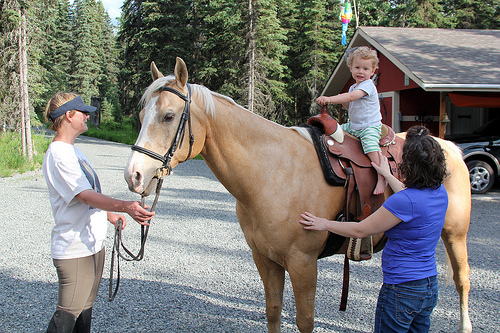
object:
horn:
[322, 96, 330, 111]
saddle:
[310, 101, 411, 218]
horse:
[125, 56, 473, 332]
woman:
[44, 91, 156, 333]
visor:
[48, 94, 97, 120]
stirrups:
[346, 234, 376, 261]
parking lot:
[0, 154, 499, 331]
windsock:
[337, 1, 354, 46]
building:
[316, 26, 500, 147]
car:
[454, 140, 500, 194]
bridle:
[131, 75, 194, 177]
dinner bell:
[442, 113, 451, 135]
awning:
[450, 91, 500, 107]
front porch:
[399, 89, 499, 137]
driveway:
[0, 124, 176, 167]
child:
[314, 45, 393, 194]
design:
[130, 95, 160, 165]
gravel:
[0, 134, 500, 332]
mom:
[300, 126, 450, 332]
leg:
[360, 131, 392, 194]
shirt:
[381, 183, 449, 285]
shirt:
[44, 143, 111, 254]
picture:
[78, 158, 101, 194]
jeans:
[374, 277, 438, 332]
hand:
[317, 96, 330, 105]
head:
[125, 56, 209, 198]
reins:
[109, 177, 163, 300]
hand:
[109, 212, 126, 229]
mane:
[141, 73, 218, 121]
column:
[438, 91, 448, 139]